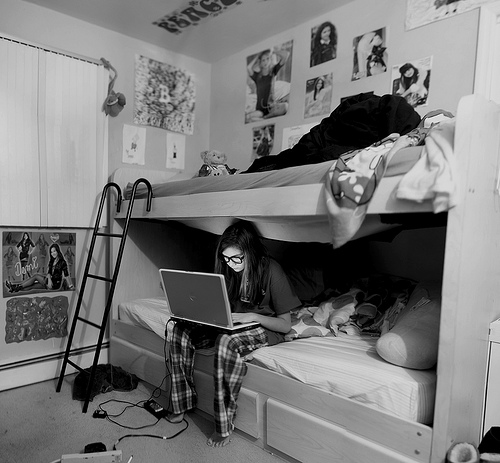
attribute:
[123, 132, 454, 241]
bed — Made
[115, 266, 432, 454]
bed — Unmade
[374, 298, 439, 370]
pillow — White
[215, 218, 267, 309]
hair — long, black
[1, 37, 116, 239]
window blinds — white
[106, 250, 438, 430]
bedcovers — White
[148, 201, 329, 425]
laptop — Open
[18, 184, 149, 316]
ladder — black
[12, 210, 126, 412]
pictures — Hung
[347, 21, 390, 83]
poster — Hung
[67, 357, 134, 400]
towel — crumpled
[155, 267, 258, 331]
laptop computer — Open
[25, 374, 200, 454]
floor — Grey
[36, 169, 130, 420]
lader — black 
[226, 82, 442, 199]
cloth — Black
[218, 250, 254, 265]
eyeglasses — black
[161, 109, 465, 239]
blankets — Balled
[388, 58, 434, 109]
poster — Hung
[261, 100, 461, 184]
clothes — Scatterer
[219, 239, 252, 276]
glasses — dark, thick-rimmed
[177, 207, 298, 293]
hair — long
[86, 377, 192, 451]
electric wires — black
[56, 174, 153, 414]
ladder — black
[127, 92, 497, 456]
bunk bed — large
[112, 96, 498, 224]
bed — wood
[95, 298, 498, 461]
bed — wood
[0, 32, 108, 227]
vertical blinds — closed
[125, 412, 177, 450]
cord — black  , long 